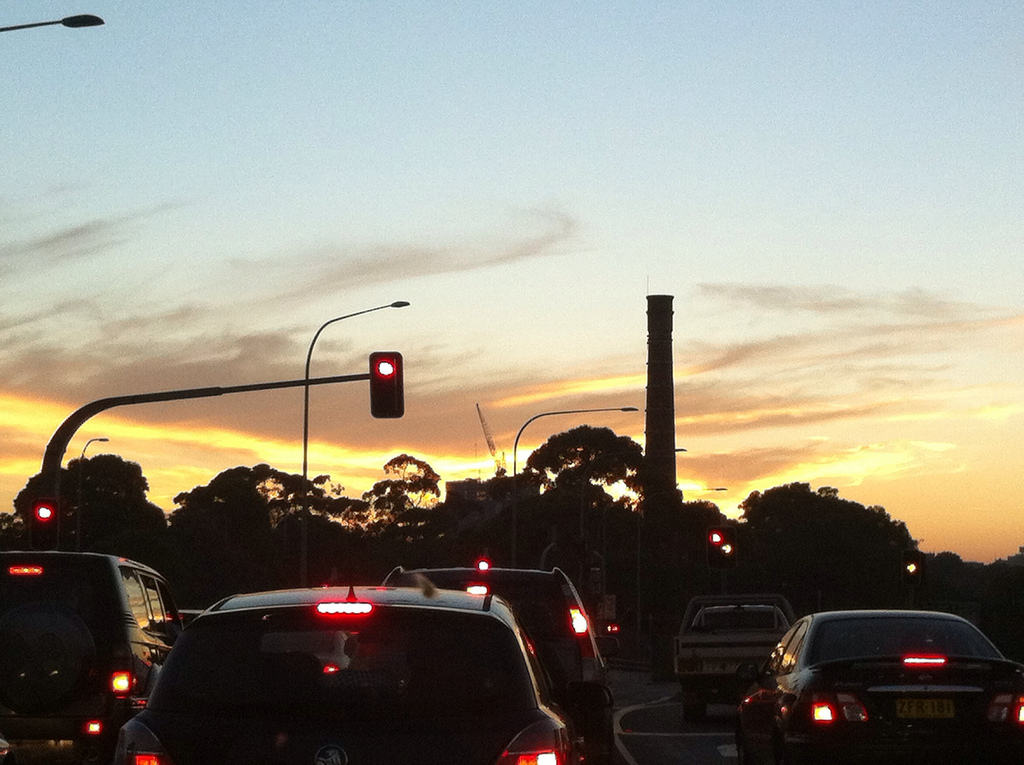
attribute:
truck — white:
[664, 584, 792, 718]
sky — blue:
[14, 31, 993, 332]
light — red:
[374, 354, 400, 394]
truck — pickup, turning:
[674, 575, 778, 682]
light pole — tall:
[296, 281, 415, 482]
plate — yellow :
[884, 697, 964, 730]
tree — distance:
[518, 413, 653, 496]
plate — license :
[859, 703, 993, 732]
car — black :
[739, 588, 979, 731]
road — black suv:
[637, 733, 724, 760]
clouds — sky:
[19, 26, 951, 415]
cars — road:
[23, 523, 981, 738]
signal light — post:
[354, 342, 415, 414]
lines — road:
[624, 701, 702, 753]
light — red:
[901, 638, 949, 680]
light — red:
[313, 592, 372, 621]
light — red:
[799, 696, 838, 729]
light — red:
[555, 597, 603, 645]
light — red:
[30, 491, 59, 524]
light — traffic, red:
[361, 344, 422, 437]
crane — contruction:
[469, 396, 515, 476]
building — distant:
[441, 463, 550, 531]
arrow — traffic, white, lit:
[713, 539, 742, 553]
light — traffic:
[365, 348, 426, 446]